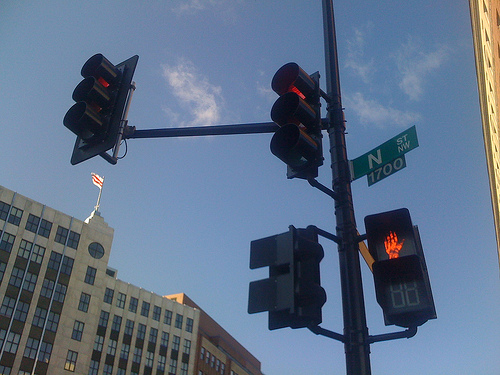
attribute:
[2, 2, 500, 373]
sky — blue, clear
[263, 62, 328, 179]
light — orange, red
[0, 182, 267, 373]
building — brown, multi-story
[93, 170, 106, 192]
flag — red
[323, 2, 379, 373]
pole — black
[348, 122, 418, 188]
sign — street, green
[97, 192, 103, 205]
pole — silver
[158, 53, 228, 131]
cloud — wispy, white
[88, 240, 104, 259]
window — circular, circle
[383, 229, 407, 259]
hand — red